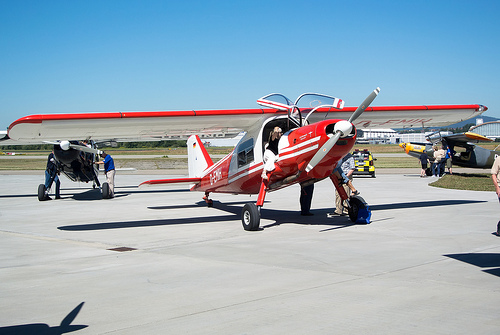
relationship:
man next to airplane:
[87, 149, 133, 202] [6, 60, 490, 273]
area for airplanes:
[11, 164, 457, 334] [6, 60, 490, 273]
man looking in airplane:
[87, 149, 133, 202] [6, 89, 490, 234]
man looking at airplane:
[87, 149, 133, 202] [6, 89, 490, 234]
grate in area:
[96, 230, 171, 280] [11, 164, 457, 334]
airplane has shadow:
[6, 60, 490, 273] [74, 195, 261, 250]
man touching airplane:
[87, 149, 133, 202] [6, 60, 490, 273]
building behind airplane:
[355, 132, 452, 162] [6, 60, 490, 273]